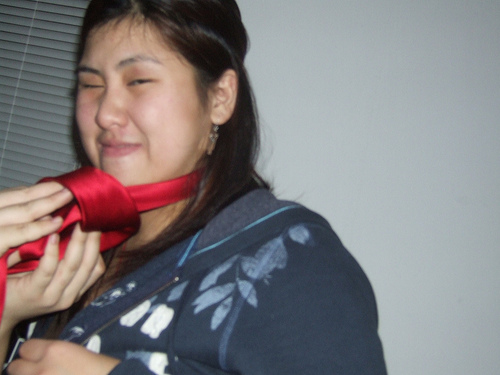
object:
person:
[0, 181, 107, 372]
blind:
[0, 1, 87, 192]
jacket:
[0, 193, 317, 375]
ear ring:
[206, 118, 224, 154]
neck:
[104, 176, 208, 245]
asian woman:
[0, 1, 387, 374]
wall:
[380, 5, 497, 373]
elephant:
[200, 118, 220, 154]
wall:
[266, 0, 343, 170]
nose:
[92, 86, 130, 131]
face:
[72, 21, 209, 186]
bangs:
[83, 9, 163, 55]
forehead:
[70, 10, 174, 66]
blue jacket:
[0, 187, 388, 373]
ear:
[208, 68, 239, 125]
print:
[190, 224, 312, 333]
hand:
[0, 182, 73, 259]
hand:
[0, 223, 109, 324]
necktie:
[0, 165, 202, 326]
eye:
[77, 75, 104, 92]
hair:
[192, 10, 237, 65]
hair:
[68, 0, 271, 313]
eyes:
[124, 76, 158, 88]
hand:
[6, 338, 123, 375]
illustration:
[58, 203, 309, 375]